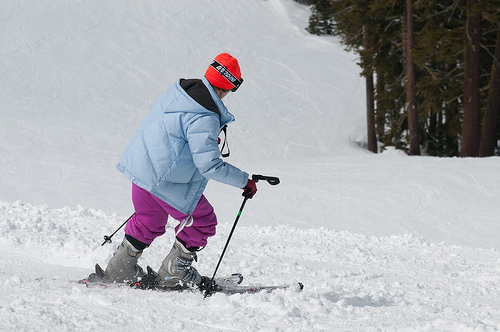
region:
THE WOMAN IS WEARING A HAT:
[203, 50, 247, 95]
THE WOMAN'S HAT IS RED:
[202, 49, 246, 96]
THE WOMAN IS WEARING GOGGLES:
[208, 57, 243, 95]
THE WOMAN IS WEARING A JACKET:
[113, 71, 250, 213]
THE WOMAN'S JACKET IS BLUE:
[111, 72, 251, 219]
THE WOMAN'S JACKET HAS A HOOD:
[115, 75, 251, 218]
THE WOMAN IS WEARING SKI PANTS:
[123, 178, 221, 258]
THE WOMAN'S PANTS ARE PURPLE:
[123, 177, 219, 252]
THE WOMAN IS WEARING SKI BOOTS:
[102, 232, 214, 295]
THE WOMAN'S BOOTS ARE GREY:
[101, 235, 205, 291]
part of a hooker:
[200, 202, 246, 301]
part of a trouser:
[182, 215, 222, 270]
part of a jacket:
[149, 135, 189, 173]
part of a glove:
[237, 167, 262, 194]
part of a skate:
[281, 266, 325, 323]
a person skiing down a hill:
[111, 42, 308, 294]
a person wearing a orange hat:
[197, 53, 265, 104]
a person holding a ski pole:
[178, 47, 289, 294]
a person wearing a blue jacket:
[119, 47, 260, 214]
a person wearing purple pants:
[97, 57, 274, 284]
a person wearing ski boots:
[103, 63, 255, 305]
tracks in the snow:
[327, 158, 466, 274]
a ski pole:
[213, 157, 293, 316]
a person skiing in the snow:
[77, 43, 281, 302]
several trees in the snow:
[307, 29, 482, 170]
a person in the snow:
[59, 5, 292, 328]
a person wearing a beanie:
[89, 20, 384, 304]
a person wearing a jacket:
[82, 2, 312, 303]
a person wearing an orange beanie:
[62, 20, 274, 303]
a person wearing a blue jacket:
[61, 18, 329, 327]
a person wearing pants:
[75, 20, 301, 302]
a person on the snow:
[89, 35, 282, 303]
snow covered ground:
[305, 245, 440, 309]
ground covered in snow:
[342, 210, 472, 331]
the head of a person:
[203, 48, 246, 100]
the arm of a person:
[186, 127, 246, 191]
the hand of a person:
[238, 175, 264, 201]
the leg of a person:
[157, 185, 220, 254]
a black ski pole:
[199, 167, 284, 302]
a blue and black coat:
[109, 68, 254, 220]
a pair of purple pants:
[116, 175, 223, 259]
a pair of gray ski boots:
[97, 232, 213, 292]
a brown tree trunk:
[458, 11, 486, 156]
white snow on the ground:
[1, 0, 498, 330]